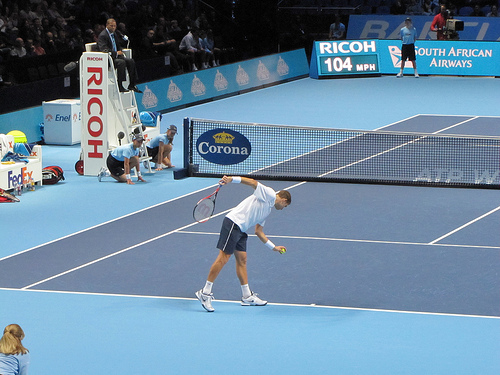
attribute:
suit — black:
[96, 15, 144, 93]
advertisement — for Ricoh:
[317, 40, 379, 56]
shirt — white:
[224, 181, 280, 234]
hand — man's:
[226, 171, 246, 184]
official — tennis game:
[97, 17, 140, 109]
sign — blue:
[193, 127, 252, 169]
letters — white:
[198, 140, 245, 160]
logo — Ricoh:
[78, 48, 112, 177]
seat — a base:
[92, 114, 186, 182]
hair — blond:
[0, 322, 28, 354]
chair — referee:
[80, 51, 150, 181]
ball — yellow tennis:
[274, 243, 300, 255]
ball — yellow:
[275, 239, 298, 261]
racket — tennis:
[192, 181, 221, 226]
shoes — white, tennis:
[194, 280, 265, 313]